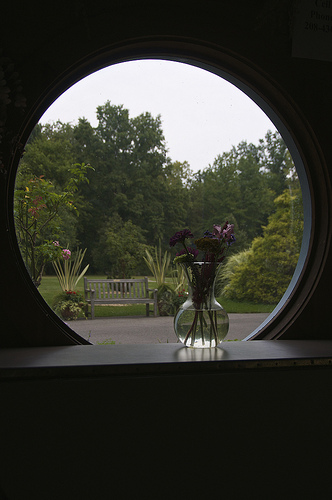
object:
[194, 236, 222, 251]
flowers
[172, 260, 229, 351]
vase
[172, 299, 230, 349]
bottom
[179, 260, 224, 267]
opening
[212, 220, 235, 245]
flower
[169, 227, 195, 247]
flower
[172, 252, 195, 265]
flower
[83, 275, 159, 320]
bench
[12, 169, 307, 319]
garden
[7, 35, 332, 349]
window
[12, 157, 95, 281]
tree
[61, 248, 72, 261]
flower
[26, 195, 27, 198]
leaves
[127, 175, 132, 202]
trees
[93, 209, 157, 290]
tree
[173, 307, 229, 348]
water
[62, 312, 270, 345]
pavement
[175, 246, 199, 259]
flower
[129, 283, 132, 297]
slat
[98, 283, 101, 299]
slat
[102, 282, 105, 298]
slat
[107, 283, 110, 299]
slat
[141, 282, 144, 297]
slat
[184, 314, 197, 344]
stems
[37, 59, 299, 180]
sky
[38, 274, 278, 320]
grass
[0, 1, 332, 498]
interior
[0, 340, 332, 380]
shelf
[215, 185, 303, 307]
bush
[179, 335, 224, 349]
light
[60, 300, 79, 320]
pot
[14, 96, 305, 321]
forest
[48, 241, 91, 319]
plant